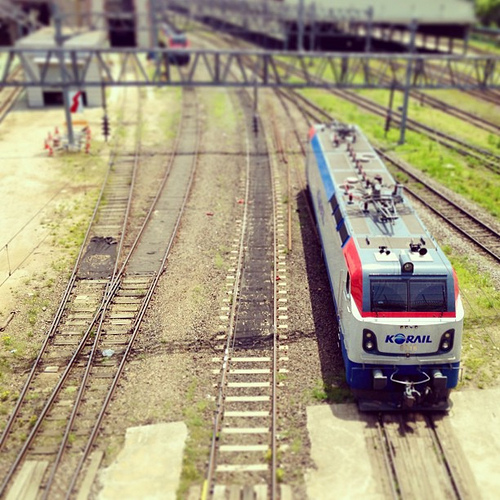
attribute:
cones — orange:
[36, 122, 102, 165]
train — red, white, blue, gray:
[297, 106, 467, 418]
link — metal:
[368, 361, 449, 404]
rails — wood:
[199, 352, 288, 499]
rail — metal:
[2, 39, 498, 95]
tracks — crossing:
[42, 204, 176, 394]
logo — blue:
[381, 328, 437, 348]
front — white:
[350, 317, 462, 364]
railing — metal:
[2, 44, 498, 94]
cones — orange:
[37, 119, 95, 159]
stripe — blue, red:
[299, 117, 464, 320]